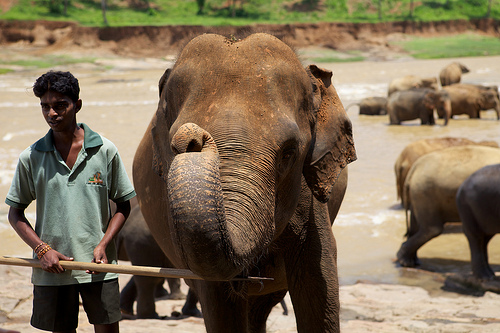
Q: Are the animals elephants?
A: Yes, all the animals are elephants.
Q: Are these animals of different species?
A: No, all the animals are elephants.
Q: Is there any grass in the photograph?
A: Yes, there is grass.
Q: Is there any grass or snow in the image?
A: Yes, there is grass.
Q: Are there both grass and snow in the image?
A: No, there is grass but no snow.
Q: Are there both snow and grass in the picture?
A: No, there is grass but no snow.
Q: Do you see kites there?
A: No, there are no kites.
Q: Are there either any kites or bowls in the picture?
A: No, there are no kites or bowls.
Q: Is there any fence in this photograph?
A: No, there are no fences.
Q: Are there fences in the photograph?
A: No, there are no fences.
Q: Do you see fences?
A: No, there are no fences.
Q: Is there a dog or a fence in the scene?
A: No, there are no fences or dogs.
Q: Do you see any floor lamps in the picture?
A: No, there are no floor lamps.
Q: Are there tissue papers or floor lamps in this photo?
A: No, there are no floor lamps or tissue papers.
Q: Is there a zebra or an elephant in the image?
A: Yes, there is an elephant.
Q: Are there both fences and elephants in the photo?
A: No, there is an elephant but no fences.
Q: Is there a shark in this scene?
A: No, there are no sharks.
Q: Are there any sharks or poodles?
A: No, there are no sharks or poodles.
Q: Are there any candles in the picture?
A: No, there are no candles.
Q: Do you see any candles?
A: No, there are no candles.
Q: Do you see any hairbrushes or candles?
A: No, there are no candles or hairbrushes.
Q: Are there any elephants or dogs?
A: Yes, there is an elephant.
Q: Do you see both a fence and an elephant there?
A: No, there is an elephant but no fences.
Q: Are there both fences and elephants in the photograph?
A: No, there is an elephant but no fences.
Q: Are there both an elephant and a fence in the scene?
A: No, there is an elephant but no fences.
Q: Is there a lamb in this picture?
A: No, there are no lambs.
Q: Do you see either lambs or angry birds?
A: No, there are no lambs or angry birds.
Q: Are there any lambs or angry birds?
A: No, there are no lambs or angry birds.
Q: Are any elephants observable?
A: Yes, there is an elephant.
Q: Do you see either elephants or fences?
A: Yes, there is an elephant.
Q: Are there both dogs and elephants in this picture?
A: No, there is an elephant but no dogs.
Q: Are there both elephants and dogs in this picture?
A: No, there is an elephant but no dogs.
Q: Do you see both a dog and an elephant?
A: No, there is an elephant but no dogs.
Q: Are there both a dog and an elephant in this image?
A: No, there is an elephant but no dogs.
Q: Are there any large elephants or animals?
A: Yes, there is a large elephant.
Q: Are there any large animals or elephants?
A: Yes, there is a large elephant.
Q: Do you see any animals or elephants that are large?
A: Yes, the elephant is large.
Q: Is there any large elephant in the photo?
A: Yes, there is a large elephant.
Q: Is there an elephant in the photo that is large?
A: Yes, there is an elephant that is large.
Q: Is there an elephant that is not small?
A: Yes, there is a large elephant.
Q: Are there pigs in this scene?
A: No, there are no pigs.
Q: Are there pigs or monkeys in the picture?
A: No, there are no pigs or monkeys.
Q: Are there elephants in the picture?
A: Yes, there is an elephant.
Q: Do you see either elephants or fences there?
A: Yes, there is an elephant.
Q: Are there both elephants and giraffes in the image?
A: No, there is an elephant but no giraffes.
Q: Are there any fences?
A: No, there are no fences.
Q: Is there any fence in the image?
A: No, there are no fences.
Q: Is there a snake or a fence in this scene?
A: No, there are no fences or snakes.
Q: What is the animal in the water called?
A: The animal is an elephant.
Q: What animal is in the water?
A: The animal is an elephant.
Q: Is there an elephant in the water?
A: Yes, there is an elephant in the water.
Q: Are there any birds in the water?
A: No, there is an elephant in the water.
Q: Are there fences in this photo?
A: No, there are no fences.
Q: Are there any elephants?
A: Yes, there is an elephant.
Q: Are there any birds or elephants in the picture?
A: Yes, there is an elephant.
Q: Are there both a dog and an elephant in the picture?
A: No, there is an elephant but no dogs.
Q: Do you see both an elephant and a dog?
A: No, there is an elephant but no dogs.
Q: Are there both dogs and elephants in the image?
A: No, there is an elephant but no dogs.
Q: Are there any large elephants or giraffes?
A: Yes, there is a large elephant.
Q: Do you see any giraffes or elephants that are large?
A: Yes, the elephant is large.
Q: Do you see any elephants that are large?
A: Yes, there is a large elephant.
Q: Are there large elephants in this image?
A: Yes, there is a large elephant.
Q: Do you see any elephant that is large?
A: Yes, there is an elephant that is large.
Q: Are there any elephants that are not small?
A: Yes, there is a large elephant.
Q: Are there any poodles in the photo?
A: No, there are no poodles.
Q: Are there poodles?
A: No, there are no poodles.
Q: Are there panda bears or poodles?
A: No, there are no poodles or panda bears.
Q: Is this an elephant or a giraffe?
A: This is an elephant.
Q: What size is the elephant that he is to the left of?
A: The elephant is large.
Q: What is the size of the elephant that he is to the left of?
A: The elephant is large.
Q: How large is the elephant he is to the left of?
A: The elephant is large.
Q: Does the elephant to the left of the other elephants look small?
A: No, the elephant is large.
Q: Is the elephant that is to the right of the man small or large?
A: The elephant is large.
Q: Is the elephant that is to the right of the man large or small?
A: The elephant is large.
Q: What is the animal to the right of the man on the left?
A: The animal is an elephant.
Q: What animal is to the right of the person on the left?
A: The animal is an elephant.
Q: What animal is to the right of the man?
A: The animal is an elephant.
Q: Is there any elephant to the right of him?
A: Yes, there is an elephant to the right of the man.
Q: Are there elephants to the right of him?
A: Yes, there is an elephant to the right of the man.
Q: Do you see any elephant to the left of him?
A: No, the elephant is to the right of the man.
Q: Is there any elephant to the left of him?
A: No, the elephant is to the right of the man.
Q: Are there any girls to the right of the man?
A: No, there is an elephant to the right of the man.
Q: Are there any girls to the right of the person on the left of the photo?
A: No, there is an elephant to the right of the man.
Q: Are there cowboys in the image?
A: No, there are no cowboys.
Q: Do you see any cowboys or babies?
A: No, there are no cowboys or babies.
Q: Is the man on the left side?
A: Yes, the man is on the left of the image.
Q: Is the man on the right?
A: No, the man is on the left of the image.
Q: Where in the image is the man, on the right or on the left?
A: The man is on the left of the image.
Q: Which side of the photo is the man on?
A: The man is on the left of the image.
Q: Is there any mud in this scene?
A: Yes, there is mud.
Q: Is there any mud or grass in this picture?
A: Yes, there is mud.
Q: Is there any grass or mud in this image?
A: Yes, there is mud.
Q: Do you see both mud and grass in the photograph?
A: Yes, there are both mud and grass.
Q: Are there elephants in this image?
A: Yes, there are elephants.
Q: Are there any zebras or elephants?
A: Yes, there are elephants.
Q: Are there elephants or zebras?
A: Yes, there are elephants.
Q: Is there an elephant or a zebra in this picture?
A: Yes, there are elephants.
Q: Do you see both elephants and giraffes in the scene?
A: No, there are elephants but no giraffes.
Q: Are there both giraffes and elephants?
A: No, there are elephants but no giraffes.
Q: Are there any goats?
A: No, there are no goats.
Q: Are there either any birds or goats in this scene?
A: No, there are no goats or birds.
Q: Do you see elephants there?
A: Yes, there is an elephant.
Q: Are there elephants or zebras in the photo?
A: Yes, there is an elephant.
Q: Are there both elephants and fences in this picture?
A: No, there is an elephant but no fences.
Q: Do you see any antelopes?
A: No, there are no antelopes.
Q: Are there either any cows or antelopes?
A: No, there are no antelopes or cows.